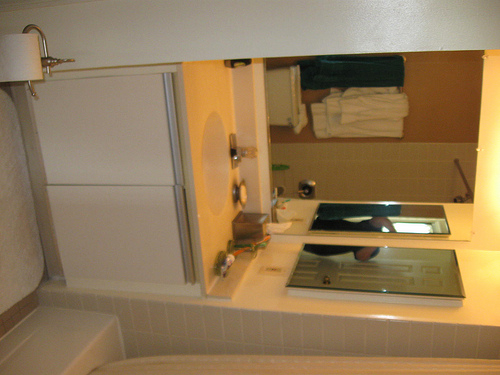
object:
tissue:
[266, 221, 293, 235]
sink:
[178, 59, 260, 302]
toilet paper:
[0, 31, 46, 84]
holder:
[22, 24, 75, 75]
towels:
[295, 54, 408, 140]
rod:
[402, 57, 405, 138]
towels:
[309, 86, 410, 140]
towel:
[295, 54, 404, 91]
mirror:
[262, 52, 481, 243]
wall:
[233, 233, 498, 327]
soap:
[241, 184, 248, 204]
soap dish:
[234, 179, 249, 210]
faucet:
[229, 133, 258, 167]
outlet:
[259, 264, 285, 276]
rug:
[0, 88, 46, 317]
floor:
[0, 292, 39, 340]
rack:
[399, 56, 408, 138]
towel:
[310, 85, 410, 138]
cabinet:
[284, 242, 465, 307]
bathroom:
[0, 0, 498, 373]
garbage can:
[265, 64, 308, 134]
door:
[28, 71, 182, 189]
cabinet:
[22, 71, 194, 292]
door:
[46, 184, 197, 296]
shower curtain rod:
[452, 153, 478, 205]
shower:
[276, 142, 477, 203]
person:
[304, 241, 381, 262]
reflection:
[305, 202, 451, 238]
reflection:
[361, 216, 397, 233]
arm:
[353, 245, 379, 263]